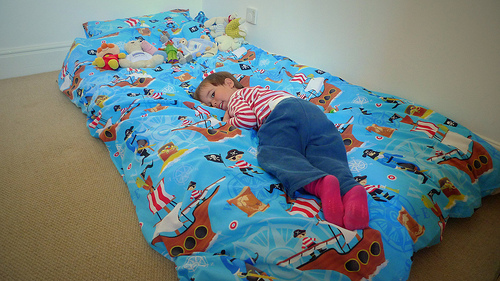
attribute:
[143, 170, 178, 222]
sail — red and white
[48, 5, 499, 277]
comforter — patterned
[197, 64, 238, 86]
hair — brown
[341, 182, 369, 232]
sock — pink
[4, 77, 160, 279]
carpet — tan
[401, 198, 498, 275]
carpet — tan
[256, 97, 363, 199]
pants — blue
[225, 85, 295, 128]
shirt — striped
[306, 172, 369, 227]
socks — pink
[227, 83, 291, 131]
shirt — red and white, striped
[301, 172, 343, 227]
sock — pink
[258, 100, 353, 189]
pajamas — blue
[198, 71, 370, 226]
child — resting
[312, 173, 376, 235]
socks — red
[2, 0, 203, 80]
wall — white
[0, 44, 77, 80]
baseboard — white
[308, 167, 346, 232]
sock — pink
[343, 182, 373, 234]
sock — pink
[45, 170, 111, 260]
carpeting — beige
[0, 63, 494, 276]
carpet — beige 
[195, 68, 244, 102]
hair — blonde